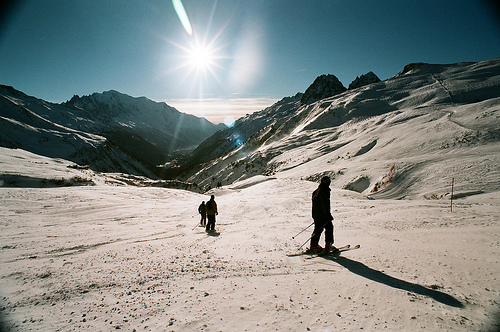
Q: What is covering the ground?
A: Snow.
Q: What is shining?
A: Sun.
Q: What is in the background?
A: Mountains.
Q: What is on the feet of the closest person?
A: Skis.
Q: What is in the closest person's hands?
A: Ski poles.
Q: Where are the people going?
A: Uphill.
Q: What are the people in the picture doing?
A: Skiing.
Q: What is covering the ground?
A: Snow.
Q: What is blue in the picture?
A: The sky.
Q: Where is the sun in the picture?
A: The middle of the sky.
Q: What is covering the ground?
A: Snow.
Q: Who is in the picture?
A: Three men.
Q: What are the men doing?
A: Skiing.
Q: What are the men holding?
A: Poles.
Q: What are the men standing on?
A: Skis.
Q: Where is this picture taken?
A: Ski slope.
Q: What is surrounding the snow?
A: Mountains.